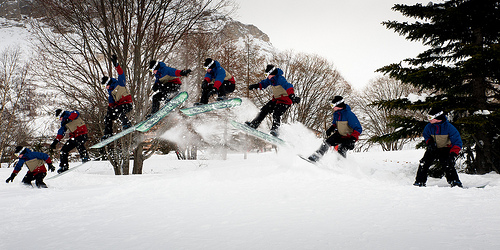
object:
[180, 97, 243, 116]
board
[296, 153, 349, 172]
board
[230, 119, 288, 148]
board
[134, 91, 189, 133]
board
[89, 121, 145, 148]
board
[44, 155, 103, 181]
board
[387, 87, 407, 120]
ground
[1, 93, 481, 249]
hill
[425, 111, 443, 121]
goggles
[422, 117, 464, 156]
jacket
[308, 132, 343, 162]
leg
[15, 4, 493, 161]
sky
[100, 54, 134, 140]
guy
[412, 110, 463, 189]
guy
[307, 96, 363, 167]
guy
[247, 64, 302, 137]
guy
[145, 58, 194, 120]
guy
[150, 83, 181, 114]
skipants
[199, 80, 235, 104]
skipants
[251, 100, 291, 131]
skipants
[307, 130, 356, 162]
skipants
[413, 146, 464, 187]
skipants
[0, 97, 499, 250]
snow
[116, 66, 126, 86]
arm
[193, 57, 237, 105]
guy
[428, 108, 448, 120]
hat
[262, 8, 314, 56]
clouds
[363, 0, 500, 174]
pine tree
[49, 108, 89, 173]
man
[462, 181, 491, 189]
board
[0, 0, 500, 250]
photographic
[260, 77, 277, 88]
arm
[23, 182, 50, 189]
snowboard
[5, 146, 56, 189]
person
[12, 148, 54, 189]
clothes